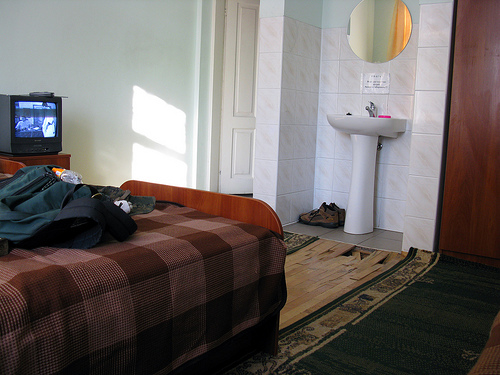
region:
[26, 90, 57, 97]
a remote control on top of the t.v.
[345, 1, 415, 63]
A round mirror is installed on a white tile wall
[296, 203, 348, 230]
a pair of brown shoes are on the floor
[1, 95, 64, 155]
the t.v. sits on a small table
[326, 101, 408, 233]
a pedestal bathroom sink is surrounded by white tile walls.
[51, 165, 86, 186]
a package of new underwear sits on a pile of clothes.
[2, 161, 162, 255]
a pile of clothes sit on the bed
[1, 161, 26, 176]
part of the foot of the 2nd bed in the room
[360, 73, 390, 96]
a sign affixed to the wall put up by management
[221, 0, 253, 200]
the door that opens to the other areas of the floor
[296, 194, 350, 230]
two shoes by a sking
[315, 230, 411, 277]
a broken wood floor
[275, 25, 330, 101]
a white tile wall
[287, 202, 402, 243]
a tile floor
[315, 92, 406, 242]
a white sink on a tile floor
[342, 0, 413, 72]
a mirror on a wall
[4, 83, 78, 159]
a television on a stand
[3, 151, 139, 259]
a backpack on a bed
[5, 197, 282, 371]
a brown patterned comforter on a bed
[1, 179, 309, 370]
a bed in a room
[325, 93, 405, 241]
A white bathroom sink.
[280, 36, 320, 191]
Tiles which are on the wall.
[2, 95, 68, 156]
A TV set, which is turned on.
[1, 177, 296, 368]
A wooden framed, small bed.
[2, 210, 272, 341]
A maroon and beige comforter, which is on the bed.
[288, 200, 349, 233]
A pair of shoes.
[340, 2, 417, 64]
A round mirror on the wall.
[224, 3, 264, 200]
A white door.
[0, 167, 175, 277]
A pile of clothes on top of the bed.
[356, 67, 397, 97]
A sign which hangs above the sink.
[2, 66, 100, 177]
A flat screen TV.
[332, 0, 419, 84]
a round mirror on a wall.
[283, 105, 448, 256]
A standing sink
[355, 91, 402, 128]
a metal faucet for a sink.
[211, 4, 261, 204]
An open door in a room.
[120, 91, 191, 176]
light from a window on a wall.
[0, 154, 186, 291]
a blanket on top of a bed.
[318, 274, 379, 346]
a rug on the floor.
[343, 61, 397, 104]
a sign posted to a wall.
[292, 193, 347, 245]
a pair of shoes on the floor.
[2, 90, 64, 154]
an old black TV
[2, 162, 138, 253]
a green backpack on the bed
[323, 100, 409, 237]
a tall white sink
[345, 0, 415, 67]
a small round mirror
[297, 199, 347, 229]
a pair of brown hiking boots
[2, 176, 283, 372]
a twin bed with a plaid bedspread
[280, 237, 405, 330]
rotting wood floor visible between the rugs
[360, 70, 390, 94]
a white sign on the wall above the sink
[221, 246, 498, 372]
a worn green area rug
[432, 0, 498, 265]
a wooden door